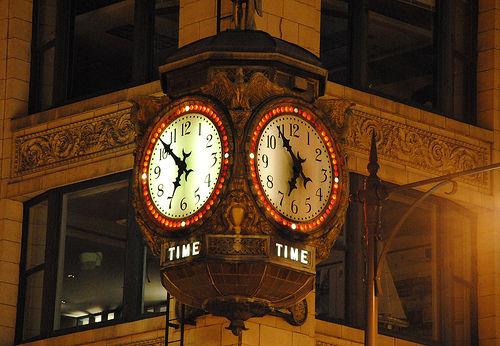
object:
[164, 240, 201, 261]
sign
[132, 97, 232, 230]
clock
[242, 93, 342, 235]
clock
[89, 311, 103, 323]
light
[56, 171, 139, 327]
window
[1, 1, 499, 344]
building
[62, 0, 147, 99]
window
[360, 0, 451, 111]
window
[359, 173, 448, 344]
window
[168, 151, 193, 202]
hour hand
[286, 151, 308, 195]
hour hand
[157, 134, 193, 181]
minute hand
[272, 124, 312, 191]
minute hand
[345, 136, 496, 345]
light pole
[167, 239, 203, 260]
word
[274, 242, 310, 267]
word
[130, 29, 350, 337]
structure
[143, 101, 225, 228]
orange ring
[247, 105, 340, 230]
orange ring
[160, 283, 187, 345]
ladder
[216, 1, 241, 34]
ladder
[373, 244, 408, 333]
sail boat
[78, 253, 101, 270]
fire alarm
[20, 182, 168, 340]
office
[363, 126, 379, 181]
point